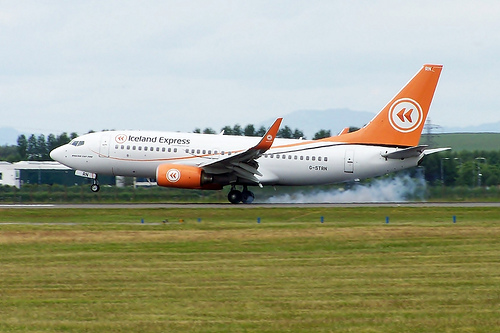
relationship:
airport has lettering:
[49, 63, 452, 204] [119, 124, 204, 154]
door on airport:
[92, 131, 121, 167] [49, 63, 452, 204]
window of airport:
[173, 132, 231, 162] [49, 63, 452, 204]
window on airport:
[173, 132, 231, 162] [49, 63, 452, 204]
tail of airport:
[333, 47, 463, 196] [49, 63, 452, 204]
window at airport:
[173, 132, 231, 162] [49, 63, 452, 204]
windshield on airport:
[56, 129, 95, 162] [49, 63, 452, 204]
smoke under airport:
[221, 171, 425, 229] [49, 63, 452, 204]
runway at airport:
[16, 185, 141, 236] [33, 62, 486, 286]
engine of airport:
[148, 158, 209, 194] [49, 63, 452, 204]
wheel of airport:
[227, 177, 253, 199] [49, 63, 452, 204]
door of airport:
[92, 131, 121, 167] [49, 63, 452, 204]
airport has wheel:
[49, 63, 452, 204] [227, 177, 253, 199]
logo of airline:
[128, 135, 190, 145] [119, 124, 204, 154]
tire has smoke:
[227, 177, 253, 199] [221, 171, 425, 229]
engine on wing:
[148, 158, 209, 194] [210, 135, 252, 173]